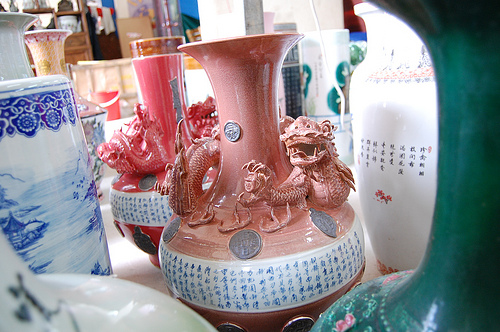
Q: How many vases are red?
A: 1.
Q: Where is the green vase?
A: In bottom right.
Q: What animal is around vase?
A: Dragon.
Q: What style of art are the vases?
A: Asian.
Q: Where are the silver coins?
A: Attached to vase.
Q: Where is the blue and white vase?
A: To the left.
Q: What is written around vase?
A: Kanji symbols.